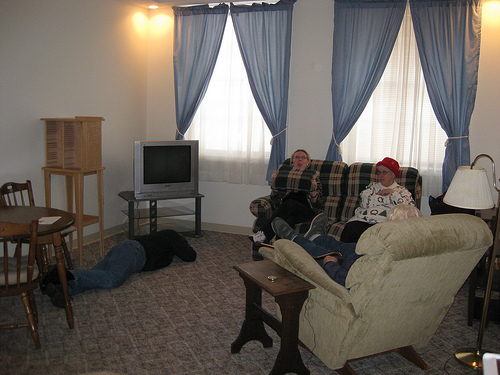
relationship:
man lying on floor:
[39, 229, 198, 310] [4, 203, 499, 373]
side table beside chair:
[231, 259, 318, 374] [257, 213, 493, 375]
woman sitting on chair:
[239, 130, 327, 257] [248, 158, 422, 262]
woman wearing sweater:
[339, 150, 425, 245] [344, 179, 413, 221]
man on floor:
[39, 229, 198, 310] [3, 223, 498, 373]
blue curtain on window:
[170, 2, 228, 141] [168, 10, 283, 152]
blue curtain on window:
[407, 0, 483, 194] [342, 7, 464, 168]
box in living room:
[39, 116, 106, 172] [0, 0, 500, 372]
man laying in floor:
[39, 229, 198, 310] [132, 296, 192, 354]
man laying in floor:
[133, 227, 195, 275] [145, 272, 198, 307]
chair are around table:
[0, 219, 40, 317] [36, 206, 77, 327]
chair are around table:
[0, 219, 40, 317] [0, 204, 75, 238]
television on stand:
[132, 139, 199, 200] [118, 130, 255, 272]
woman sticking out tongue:
[248, 148, 323, 247] [296, 162, 302, 164]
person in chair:
[275, 207, 427, 274] [257, 213, 493, 375]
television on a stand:
[126, 133, 204, 200] [118, 190, 207, 240]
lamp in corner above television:
[149, 5, 159, 8] [132, 139, 199, 200]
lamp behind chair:
[124, 10, 172, 37] [257, 213, 493, 375]